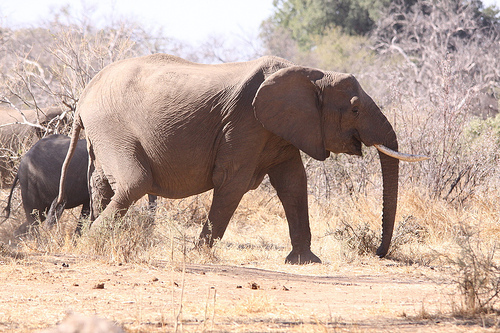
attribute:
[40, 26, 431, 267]
elephant — large, brown, walking, wild, gray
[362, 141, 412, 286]
trunk — large, long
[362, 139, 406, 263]
tusk — white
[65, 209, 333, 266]
feet — large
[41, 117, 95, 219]
tail — large, brown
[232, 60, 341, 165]
ear — large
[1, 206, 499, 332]
ground — brown, dirty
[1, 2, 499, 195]
trees — leafy, green, bare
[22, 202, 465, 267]
grass — tall, brown, dead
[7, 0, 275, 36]
sky — clear